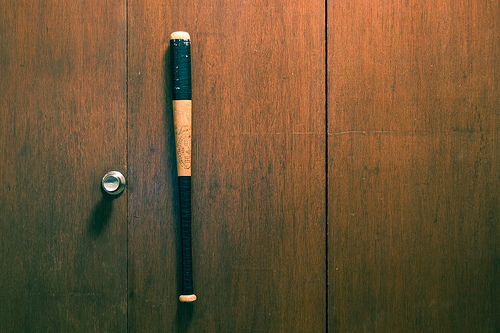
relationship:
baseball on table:
[168, 30, 198, 303] [1, 0, 498, 328]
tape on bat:
[169, 39, 193, 101] [170, 30, 196, 301]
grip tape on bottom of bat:
[176, 176, 192, 296] [170, 30, 196, 301]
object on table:
[100, 170, 126, 195] [1, 0, 498, 328]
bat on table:
[170, 30, 196, 301] [1, 0, 498, 328]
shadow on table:
[86, 190, 116, 233] [1, 0, 498, 328]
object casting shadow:
[100, 170, 126, 193] [86, 190, 116, 233]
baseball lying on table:
[168, 30, 198, 304] [1, 0, 498, 328]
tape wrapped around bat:
[176, 173, 196, 294] [168, 30, 197, 301]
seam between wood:
[321, 0, 330, 330] [1, 0, 498, 328]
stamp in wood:
[175, 123, 194, 167] [170, 30, 197, 301]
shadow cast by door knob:
[86, 180, 124, 234] [101, 168, 124, 197]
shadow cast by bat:
[177, 301, 195, 324] [168, 30, 197, 301]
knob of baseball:
[178, 292, 197, 303] [168, 30, 198, 304]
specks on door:
[361, 7, 386, 46] [0, 1, 496, 330]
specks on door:
[336, 60, 388, 136] [0, 1, 496, 330]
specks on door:
[375, 52, 435, 112] [0, 1, 496, 330]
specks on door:
[270, 26, 325, 76] [0, 1, 496, 330]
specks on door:
[203, 12, 267, 104] [0, 1, 496, 330]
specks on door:
[87, 73, 119, 122] [0, 1, 496, 330]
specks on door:
[194, 124, 266, 194] [0, 1, 496, 330]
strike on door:
[352, 259, 378, 311] [323, 5, 483, 331]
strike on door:
[70, 116, 108, 169] [1, 2, 132, 331]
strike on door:
[45, 211, 89, 286] [1, 2, 132, 331]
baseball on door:
[168, 30, 198, 304] [122, 1, 323, 329]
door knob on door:
[99, 172, 127, 197] [3, 3, 322, 330]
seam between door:
[321, 0, 330, 333] [122, 1, 323, 329]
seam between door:
[321, 0, 330, 333] [323, 2, 495, 331]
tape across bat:
[169, 39, 193, 101] [164, 27, 201, 307]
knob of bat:
[175, 290, 200, 304] [164, 27, 201, 307]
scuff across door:
[272, 128, 380, 138] [122, 1, 323, 329]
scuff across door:
[272, 128, 380, 138] [323, 2, 495, 331]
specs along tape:
[170, 59, 183, 97] [169, 39, 193, 101]